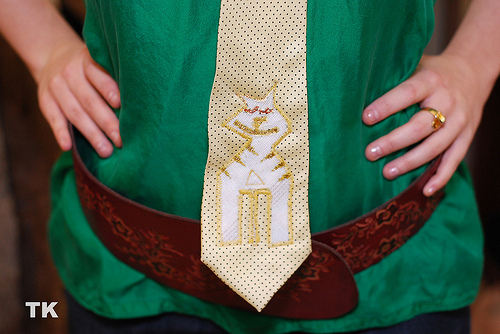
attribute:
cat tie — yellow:
[186, 4, 326, 316]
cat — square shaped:
[215, 80, 289, 245]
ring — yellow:
[421, 105, 448, 126]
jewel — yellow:
[428, 113, 451, 127]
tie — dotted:
[186, 5, 320, 317]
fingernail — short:
[57, 137, 70, 150]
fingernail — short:
[96, 142, 111, 155]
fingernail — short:
[109, 132, 121, 143]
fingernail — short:
[104, 90, 119, 104]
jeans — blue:
[66, 284, 473, 331]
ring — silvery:
[416, 105, 446, 128]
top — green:
[51, 1, 488, 325]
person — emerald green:
[2, 1, 482, 328]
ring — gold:
[416, 103, 446, 132]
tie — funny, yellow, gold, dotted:
[199, 3, 315, 310]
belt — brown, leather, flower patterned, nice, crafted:
[69, 130, 447, 314]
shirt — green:
[50, 3, 486, 318]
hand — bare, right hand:
[35, 42, 121, 156]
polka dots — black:
[199, 0, 313, 313]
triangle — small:
[243, 169, 267, 189]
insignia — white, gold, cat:
[216, 76, 293, 246]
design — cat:
[218, 77, 293, 247]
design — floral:
[328, 198, 435, 272]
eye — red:
[245, 106, 258, 115]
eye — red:
[259, 104, 272, 115]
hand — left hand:
[360, 50, 499, 196]